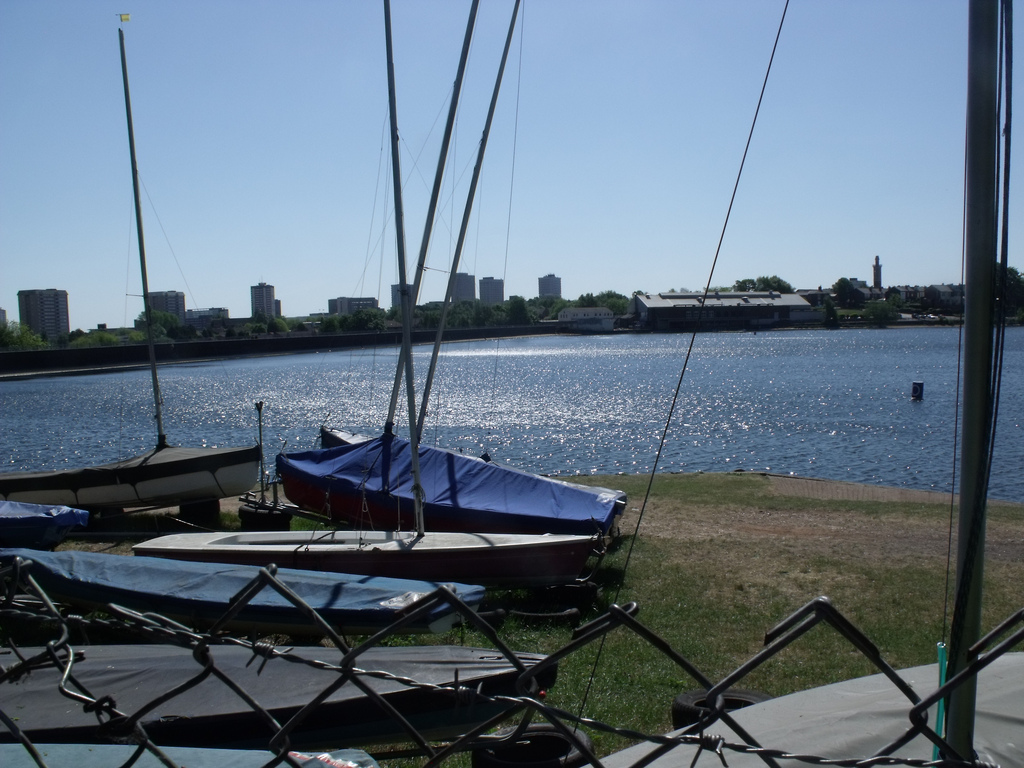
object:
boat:
[274, 432, 627, 557]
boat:
[0, 444, 263, 509]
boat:
[131, 531, 611, 591]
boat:
[11, 547, 487, 637]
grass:
[351, 471, 1024, 768]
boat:
[0, 644, 559, 754]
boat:
[0, 744, 381, 768]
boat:
[588, 650, 1024, 768]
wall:
[39, 294, 69, 342]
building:
[17, 289, 71, 341]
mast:
[117, 13, 167, 450]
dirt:
[614, 487, 1020, 589]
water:
[0, 323, 1024, 501]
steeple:
[873, 256, 882, 291]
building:
[629, 289, 827, 329]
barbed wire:
[0, 557, 1024, 768]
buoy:
[911, 380, 925, 400]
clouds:
[0, 0, 1024, 332]